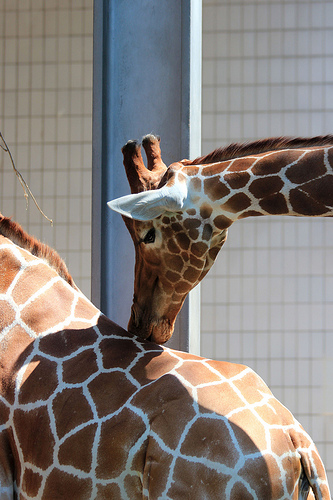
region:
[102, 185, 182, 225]
His ear is white.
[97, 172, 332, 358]
he is touching the other giraffe.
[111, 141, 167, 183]
His horns are brown.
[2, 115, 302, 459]
The giraffes are brown.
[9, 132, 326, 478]
The giraffes are spotted.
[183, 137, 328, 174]
The mane is brown.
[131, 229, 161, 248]
His eye is black.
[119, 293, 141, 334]
His nose is tan.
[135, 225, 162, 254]
He has long eyelashes.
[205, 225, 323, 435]
The wall is white.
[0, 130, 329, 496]
Two giraffes in front of a building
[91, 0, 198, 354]
Very tall window in white building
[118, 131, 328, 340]
Giraffe nibbling on the back of a second giraffe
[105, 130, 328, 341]
Head and neck of giraffe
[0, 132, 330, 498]
Two large African herbivores with brown spots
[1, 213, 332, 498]
Rear part of giraffe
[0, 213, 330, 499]
Giraffe having back nibbled by other giraffe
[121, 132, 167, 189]
Horns on head of giraffe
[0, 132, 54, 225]
Twig of tree above giraffe's neck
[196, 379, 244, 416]
Pentagon-shaped brown spot on giraffe's hindquarters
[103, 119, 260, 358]
The giraffe is kissing another giraffe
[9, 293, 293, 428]
The giraffe is brown and white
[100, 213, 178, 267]
The giraffe is shown one eye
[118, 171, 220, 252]
The giraffe has a white ear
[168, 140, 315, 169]
The giraffe has hair on the neck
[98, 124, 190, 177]
The giraffe has two ears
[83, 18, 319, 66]
A metal pole is behind the giraffe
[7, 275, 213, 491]
A shade is on the giraffe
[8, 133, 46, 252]
A branch is next to the giraffe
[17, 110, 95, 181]
The back wall is white tile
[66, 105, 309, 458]
giraffe kissing another giraffe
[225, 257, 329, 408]
the wall is tiled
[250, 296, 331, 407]
the tiles are white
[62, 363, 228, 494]
giraffe coats are spotted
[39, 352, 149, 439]
giraffe spots are brown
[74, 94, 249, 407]
this giraffe is grooming another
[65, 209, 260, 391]
a steel beam behind the giraffe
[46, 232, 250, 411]
the giraffes are in captivity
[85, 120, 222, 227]
a giraffe has two horns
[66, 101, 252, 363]
the ear is white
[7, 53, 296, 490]
two giraffes photographed in the zoo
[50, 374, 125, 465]
brown spots on giraffe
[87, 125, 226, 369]
giraffe licking another giraffe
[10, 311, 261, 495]
shadow of giraffe on other giraffes back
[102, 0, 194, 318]
tall skinny silver door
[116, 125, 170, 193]
two horns on giraffe head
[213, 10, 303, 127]
white tile building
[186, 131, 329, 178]
hair on neck of giraffe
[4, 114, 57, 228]
small tree branch visible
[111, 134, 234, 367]
giraffe cleaning the other giraffe